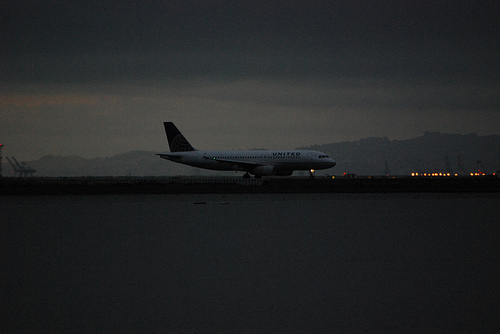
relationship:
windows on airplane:
[198, 152, 305, 163] [154, 121, 337, 179]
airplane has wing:
[154, 121, 337, 179] [204, 153, 261, 169]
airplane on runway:
[154, 121, 337, 179] [142, 165, 412, 211]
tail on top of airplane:
[155, 116, 198, 156] [141, 104, 341, 191]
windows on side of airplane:
[213, 155, 301, 159] [152, 119, 337, 181]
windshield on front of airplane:
[313, 152, 337, 169] [152, 119, 337, 181]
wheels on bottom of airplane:
[238, 174, 253, 181] [152, 119, 337, 181]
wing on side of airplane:
[195, 156, 268, 174] [173, 116, 348, 186]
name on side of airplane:
[218, 150, 298, 161] [152, 119, 337, 181]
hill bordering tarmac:
[0, 130, 500, 176] [6, 174, 498, 188]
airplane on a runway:
[154, 121, 337, 179] [0, 171, 499, 196]